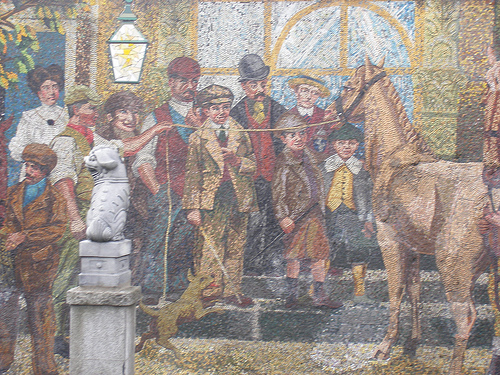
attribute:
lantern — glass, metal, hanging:
[104, 2, 149, 85]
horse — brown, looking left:
[322, 56, 499, 373]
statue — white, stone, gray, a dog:
[66, 146, 145, 374]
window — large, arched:
[191, 2, 419, 111]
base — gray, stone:
[64, 238, 142, 374]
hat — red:
[168, 55, 202, 80]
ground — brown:
[134, 336, 499, 372]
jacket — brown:
[0, 181, 72, 289]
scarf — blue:
[22, 180, 48, 209]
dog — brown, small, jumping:
[135, 268, 225, 356]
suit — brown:
[274, 149, 328, 258]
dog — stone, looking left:
[80, 145, 130, 239]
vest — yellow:
[328, 166, 355, 215]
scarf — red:
[69, 123, 95, 149]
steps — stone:
[189, 266, 497, 347]